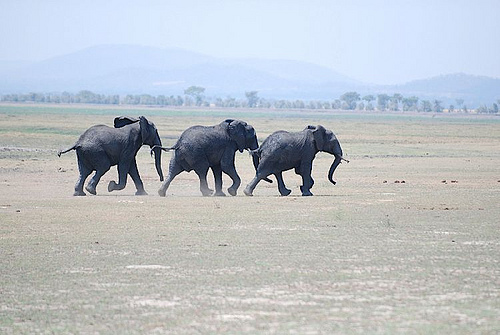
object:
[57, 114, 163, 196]
elephant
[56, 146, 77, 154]
tail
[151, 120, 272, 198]
elephant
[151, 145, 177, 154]
tail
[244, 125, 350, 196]
elephant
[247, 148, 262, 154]
tail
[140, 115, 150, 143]
ears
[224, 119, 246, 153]
ears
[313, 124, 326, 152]
ears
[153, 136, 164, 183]
trunk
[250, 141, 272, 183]
trunk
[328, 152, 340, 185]
trunk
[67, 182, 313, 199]
dust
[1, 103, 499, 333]
grass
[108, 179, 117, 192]
foot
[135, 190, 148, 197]
foot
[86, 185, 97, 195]
foot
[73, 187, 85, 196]
foot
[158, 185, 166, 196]
foot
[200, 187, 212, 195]
foot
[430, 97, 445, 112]
trees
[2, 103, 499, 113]
edge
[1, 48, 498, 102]
mountains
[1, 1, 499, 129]
distance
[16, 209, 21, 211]
rock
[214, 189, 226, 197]
foot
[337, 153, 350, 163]
tusk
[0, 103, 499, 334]
plain